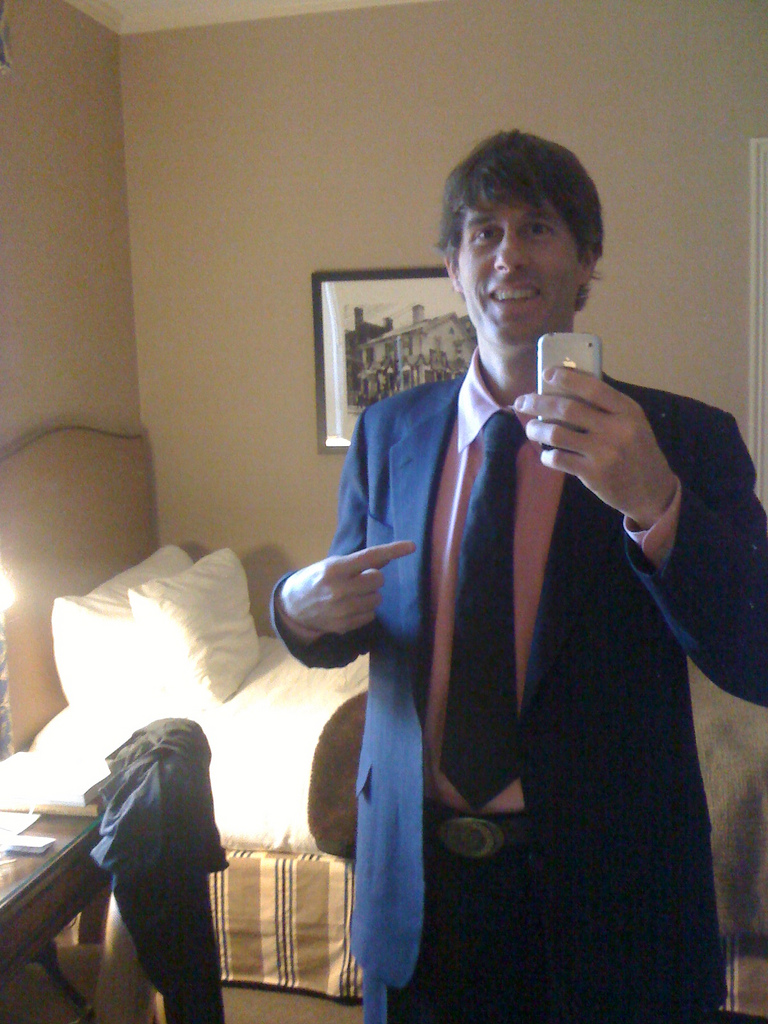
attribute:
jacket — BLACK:
[78, 714, 232, 1007]